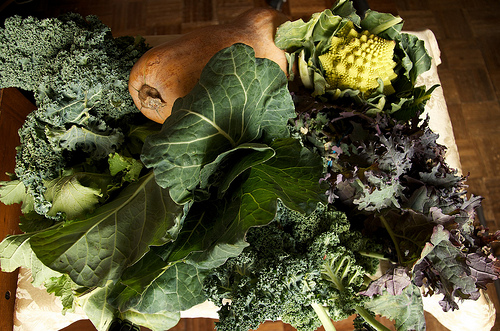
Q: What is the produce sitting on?
A: A table.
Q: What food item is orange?
A: A squash.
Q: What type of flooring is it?
A: Wood.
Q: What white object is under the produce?
A: A towel.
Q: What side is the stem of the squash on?
A: The left.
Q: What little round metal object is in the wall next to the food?
A: A screw.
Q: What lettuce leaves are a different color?
A: The ones on the right.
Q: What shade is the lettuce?
A: Green.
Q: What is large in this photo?
A: The leaf.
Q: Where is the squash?
A: Under the lettuce.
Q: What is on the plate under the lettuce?
A: The squash.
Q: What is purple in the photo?
A: The lettuce.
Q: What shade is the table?
A: Brown.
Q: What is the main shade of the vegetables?
A: Green.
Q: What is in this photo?
A: Bunch of vegetables on table.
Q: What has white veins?
A: A leaf.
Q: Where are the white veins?
A: On a leaft.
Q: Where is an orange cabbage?
A: In middle of leaves.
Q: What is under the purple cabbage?
A: Green leaves.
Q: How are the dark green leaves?
A: Large.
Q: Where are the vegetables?
A: Over a table.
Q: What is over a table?
A: A tablecloth.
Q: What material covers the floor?
A: Parquet.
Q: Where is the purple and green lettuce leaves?
A: The edge of the table.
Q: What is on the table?
A: Vegetables.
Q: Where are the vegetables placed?
A: Table.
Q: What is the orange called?
A: Squash.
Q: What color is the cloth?
A: White.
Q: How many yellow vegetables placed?
A: One.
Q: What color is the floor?
A: Brown.